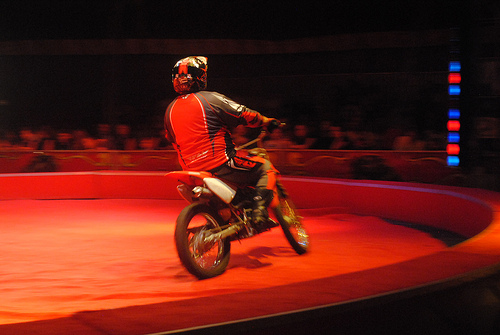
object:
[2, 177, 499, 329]
track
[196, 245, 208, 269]
spokes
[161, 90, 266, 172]
shirt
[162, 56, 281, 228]
biker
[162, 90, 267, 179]
jacket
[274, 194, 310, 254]
tire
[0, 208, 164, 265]
shining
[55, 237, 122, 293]
dirt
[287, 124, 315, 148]
people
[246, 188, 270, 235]
motocross boot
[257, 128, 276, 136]
handle bar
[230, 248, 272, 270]
shadow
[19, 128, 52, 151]
man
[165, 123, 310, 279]
bike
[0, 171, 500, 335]
pit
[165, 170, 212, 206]
muffler motorcyle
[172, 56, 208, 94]
helmet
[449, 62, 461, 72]
light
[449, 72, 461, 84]
red light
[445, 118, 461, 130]
red light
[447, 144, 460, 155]
red light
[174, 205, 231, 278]
motorcycle wheel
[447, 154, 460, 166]
light